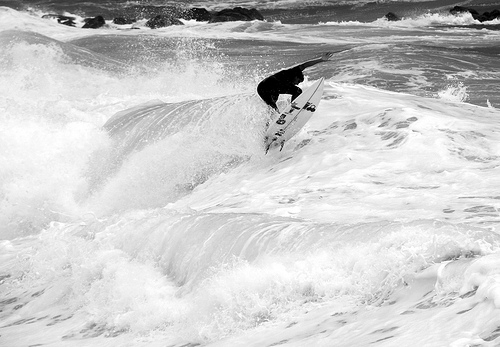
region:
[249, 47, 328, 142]
Man surfing on the ocean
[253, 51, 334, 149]
Man surfing on the ocean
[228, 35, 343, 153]
Man surfing on the ocean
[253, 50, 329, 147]
Man surfing on the ocean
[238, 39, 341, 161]
Man surfing on the ocean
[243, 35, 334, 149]
Man surfing on the ocean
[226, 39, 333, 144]
Man surfing on the ocean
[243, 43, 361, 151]
Man surfing on the ocean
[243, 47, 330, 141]
Man surfing on the ocean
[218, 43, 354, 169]
Man surfing on the ocean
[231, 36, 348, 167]
surfter in the waves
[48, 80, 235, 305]
huge white waves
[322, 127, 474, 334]
white waves in the ocean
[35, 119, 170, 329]
ocean waves in black and white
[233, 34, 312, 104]
surfer wearing a black wet suit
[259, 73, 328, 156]
bottom of a surfboard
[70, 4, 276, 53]
black rocks in the ocean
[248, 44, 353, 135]
surfer with one hand up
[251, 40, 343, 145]
a person surfing in the ocean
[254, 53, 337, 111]
A man on a surfboard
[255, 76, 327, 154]
A white surfboard riding a wave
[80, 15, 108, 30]
A black rock in the ocean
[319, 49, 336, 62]
The outstretched hand of a surfer.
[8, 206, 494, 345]
A large, foamy wave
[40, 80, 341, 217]
A wave that is currently breaking.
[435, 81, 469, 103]
A little splash of water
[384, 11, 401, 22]
A sharp pointy black rock.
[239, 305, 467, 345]
Some white foamy water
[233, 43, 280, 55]
Some clear dark water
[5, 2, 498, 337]
a black and white photo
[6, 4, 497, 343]
a scene outside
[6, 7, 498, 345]
a image of a ocean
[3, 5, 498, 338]
a scene during the day time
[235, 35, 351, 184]
a person in the water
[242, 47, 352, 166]
a surfer leaping in the air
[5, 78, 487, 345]
some large waves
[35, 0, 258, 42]
some rocks in the background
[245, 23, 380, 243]
a single person in the water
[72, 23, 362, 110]
a calm spot